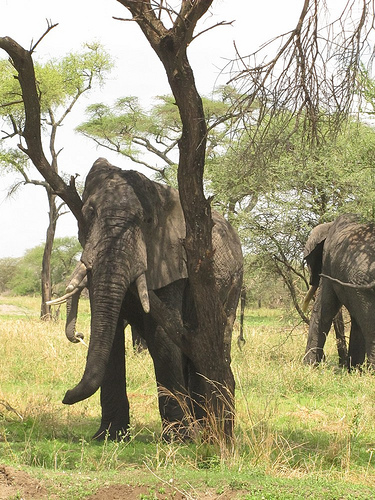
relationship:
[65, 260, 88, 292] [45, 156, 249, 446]
tusk on elephant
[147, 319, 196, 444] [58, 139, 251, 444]
front leg on elephant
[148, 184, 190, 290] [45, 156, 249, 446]
ear on elephant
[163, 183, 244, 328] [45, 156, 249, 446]
body on elephant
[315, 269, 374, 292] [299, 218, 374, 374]
tail on elephant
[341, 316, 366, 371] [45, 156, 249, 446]
right leg on elephant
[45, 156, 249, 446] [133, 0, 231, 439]
elephant on tree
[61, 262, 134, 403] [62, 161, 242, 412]
trunk on elephant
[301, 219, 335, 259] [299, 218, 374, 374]
ear on elephant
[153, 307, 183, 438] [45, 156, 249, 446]
leg on elephant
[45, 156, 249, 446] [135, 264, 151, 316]
elephant has tusk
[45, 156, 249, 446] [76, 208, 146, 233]
elephant has eyes